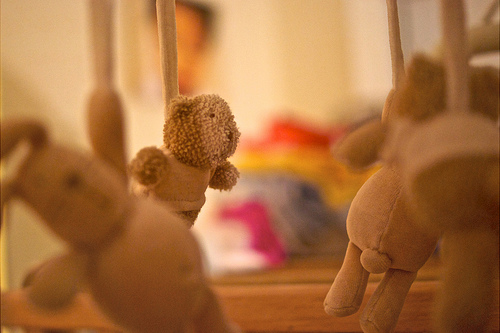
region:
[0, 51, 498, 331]
stuffed toys for an infant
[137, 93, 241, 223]
a bear wears a t-shirt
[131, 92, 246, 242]
a tiny bear with coarse fur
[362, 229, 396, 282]
a short stubby tail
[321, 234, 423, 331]
two stuffed legson a bear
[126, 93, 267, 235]
this is a teddy bear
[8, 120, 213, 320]
this is a teddy bear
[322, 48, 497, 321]
this is a teddy bear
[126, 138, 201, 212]
the teddy bear is brown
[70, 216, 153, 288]
the teddy bear is brown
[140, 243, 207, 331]
the teddy bear is brown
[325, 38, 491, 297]
Small bears on a stick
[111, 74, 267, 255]
Small bears on a stick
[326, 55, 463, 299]
Small bears on a stick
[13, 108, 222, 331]
Small bears on a stick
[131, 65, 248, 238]
Small bears on a stick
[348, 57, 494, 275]
Small bears on a stick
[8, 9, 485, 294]
Small bears on a stick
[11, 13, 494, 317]
Small bears on a stick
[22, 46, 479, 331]
Small bears on a stick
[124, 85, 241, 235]
brown stuffed teddy bear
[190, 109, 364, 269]
clothes piled in the background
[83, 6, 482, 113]
straps attached to stuffed animals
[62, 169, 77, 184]
nose of the stuffed dog toy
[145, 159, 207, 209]
shirt teddy bear is wearing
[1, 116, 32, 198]
ears of the stuffed dog toy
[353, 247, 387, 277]
tail of the stuffed animal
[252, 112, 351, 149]
red folded clothing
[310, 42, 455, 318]
Stuffed animal has a round tail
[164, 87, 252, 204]
Bear head has a different texture for head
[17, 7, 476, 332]
Stuffed animals are strange and surreal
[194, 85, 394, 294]
Bed is seen in the distance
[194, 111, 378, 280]
Bed spread is very colorful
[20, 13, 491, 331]
Stuffed animals are all floating in the air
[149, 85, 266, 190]
Stuffed animal has small beady eyes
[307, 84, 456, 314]
Seam can be seen on the stuffed animal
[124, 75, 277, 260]
stuffed bear on a pole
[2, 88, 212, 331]
stuffed bunny in the photo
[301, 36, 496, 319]
stuffed bunny in the photo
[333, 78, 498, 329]
stuffed bunny in the photo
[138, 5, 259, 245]
The teddy bear is hanging on a rope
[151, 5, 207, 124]
The rope is brown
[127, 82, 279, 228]
The teddy bear is brown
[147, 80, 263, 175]
The teddy bear has a black eye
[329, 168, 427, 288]
The teddy bear has a brown tail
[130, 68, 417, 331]
A rainbow is behind the teddy bear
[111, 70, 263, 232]
The bear is small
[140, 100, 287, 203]
The bear has an arm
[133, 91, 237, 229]
brown stuffed animal hanging from above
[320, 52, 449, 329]
brown stuffed animal hanging from above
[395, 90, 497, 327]
brown stuffed animal hanging from above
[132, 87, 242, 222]
brown stuffed animal hanging from above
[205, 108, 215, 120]
eye on the brown stuffed animal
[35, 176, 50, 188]
eye on the brown stuffed animal